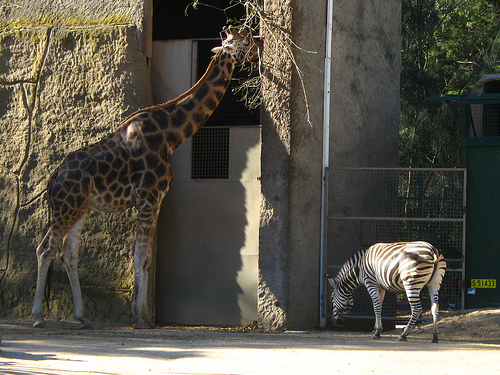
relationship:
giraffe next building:
[21, 24, 264, 332] [0, 0, 401, 336]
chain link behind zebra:
[317, 154, 477, 326] [317, 238, 451, 343]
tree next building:
[396, 4, 449, 224] [0, 0, 401, 336]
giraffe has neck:
[21, 24, 264, 332] [170, 52, 237, 149]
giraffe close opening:
[21, 28, 269, 331] [186, 33, 272, 134]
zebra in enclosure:
[317, 238, 451, 343] [8, 29, 495, 374]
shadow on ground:
[65, 330, 122, 350] [170, 349, 212, 370]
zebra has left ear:
[317, 238, 451, 343] [324, 270, 334, 285]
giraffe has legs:
[21, 28, 269, 331] [132, 201, 159, 331]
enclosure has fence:
[4, 5, 493, 335] [321, 165, 466, 335]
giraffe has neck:
[21, 28, 269, 331] [153, 55, 233, 160]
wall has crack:
[26, 18, 58, 107] [0, 23, 57, 280]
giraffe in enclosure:
[21, 24, 264, 332] [4, 5, 493, 335]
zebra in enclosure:
[317, 238, 451, 343] [4, 5, 493, 335]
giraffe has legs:
[21, 24, 264, 332] [22, 222, 91, 334]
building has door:
[0, 0, 401, 336] [148, 31, 262, 334]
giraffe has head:
[21, 24, 264, 332] [210, 20, 266, 81]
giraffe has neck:
[21, 28, 269, 331] [164, 52, 238, 152]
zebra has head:
[317, 238, 451, 343] [319, 279, 354, 333]